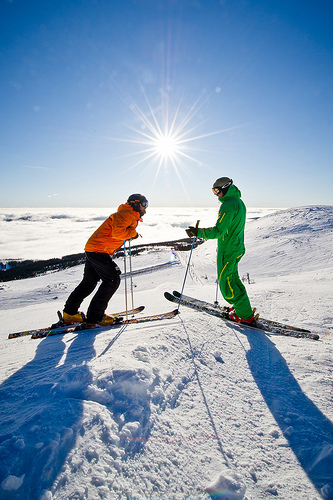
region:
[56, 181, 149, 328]
Person leaning on ski poles.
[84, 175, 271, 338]
There are two skiers.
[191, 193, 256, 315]
The skier is wearing green.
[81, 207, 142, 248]
The jacket is orange.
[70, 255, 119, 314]
The pants are black.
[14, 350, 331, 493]
Snow on the ground.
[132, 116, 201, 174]
The sun is shining.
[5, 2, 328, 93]
The sky is blue.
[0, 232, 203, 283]
Brown under the snow.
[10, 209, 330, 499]
Taken on a mountain.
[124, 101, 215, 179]
very bright sun shinning in the sky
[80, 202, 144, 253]
orange ski jacket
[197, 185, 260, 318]
green snow suit with yellow trim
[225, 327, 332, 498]
a man's shadow in the snow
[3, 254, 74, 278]
line of trees going up the mountain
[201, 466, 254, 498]
round clump of snow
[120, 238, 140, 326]
ski poles stuck in the snow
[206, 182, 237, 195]
goggles to protect the eyes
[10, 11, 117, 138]
blue sky with no clouds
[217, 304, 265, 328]
red ski boots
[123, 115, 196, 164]
sun in the sky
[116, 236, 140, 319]
poles in the snow covered ground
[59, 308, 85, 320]
boot on skier foot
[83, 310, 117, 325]
boot on skier foot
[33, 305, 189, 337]
ski on skier foot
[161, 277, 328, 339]
skis on skier foot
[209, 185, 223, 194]
goggles on skier face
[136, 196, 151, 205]
goggles on skier face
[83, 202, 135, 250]
jacket on skier's body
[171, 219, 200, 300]
pole in skier's hand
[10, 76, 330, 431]
men standing on snowy hill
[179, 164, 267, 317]
man wearing green coveralls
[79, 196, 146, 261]
man wearing orange jacket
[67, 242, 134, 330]
man wearing black pants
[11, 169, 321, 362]
men wearing skis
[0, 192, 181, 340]
man leaning on ski poles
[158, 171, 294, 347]
man holding ski pole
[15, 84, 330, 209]
sun up in background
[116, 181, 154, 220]
man wearing black hat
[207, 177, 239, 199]
man wearing reflective goggles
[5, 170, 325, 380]
two skiers face to face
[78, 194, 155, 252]
this skier wears an orange jacket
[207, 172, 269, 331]
this skier is wearing all green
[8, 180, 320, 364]
they appear to be cross country skiing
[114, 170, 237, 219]
both are wearing goggles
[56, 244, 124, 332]
this skier has on black pants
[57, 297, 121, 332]
this person has yellow ski boots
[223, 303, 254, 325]
this skiier has on red ski boots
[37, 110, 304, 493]
it appears to be a beautiful day for skiing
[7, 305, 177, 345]
this person's skis are multi colored